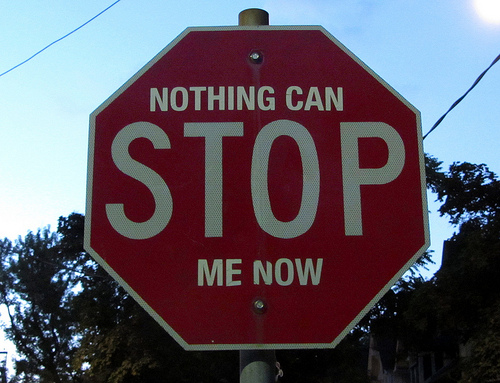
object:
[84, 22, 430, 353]
sign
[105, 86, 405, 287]
lettering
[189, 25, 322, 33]
edge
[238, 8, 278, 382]
pole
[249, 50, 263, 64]
bolt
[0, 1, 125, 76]
power line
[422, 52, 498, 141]
power line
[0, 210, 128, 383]
trees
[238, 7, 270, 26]
top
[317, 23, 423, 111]
edge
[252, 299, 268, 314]
bolt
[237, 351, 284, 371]
shadow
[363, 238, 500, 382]
house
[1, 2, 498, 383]
sky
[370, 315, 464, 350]
roof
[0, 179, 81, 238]
clouds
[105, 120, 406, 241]
stop